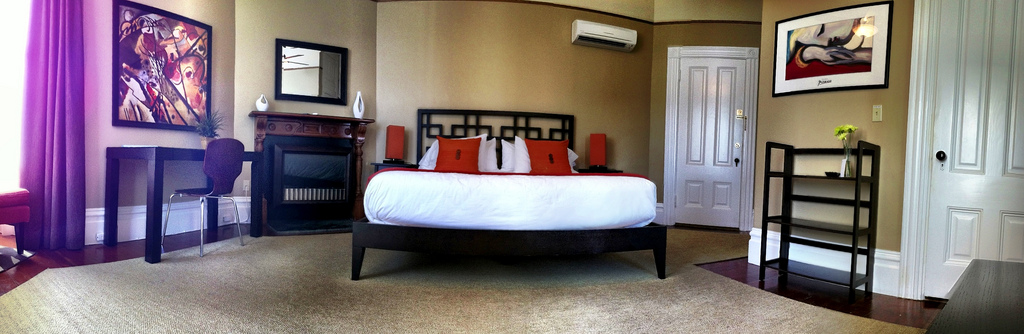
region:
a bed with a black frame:
[348, 109, 671, 284]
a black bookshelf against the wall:
[762, 141, 881, 293]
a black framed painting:
[105, 1, 213, 135]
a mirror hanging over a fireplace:
[248, 34, 378, 230]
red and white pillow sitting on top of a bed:
[354, 113, 659, 273]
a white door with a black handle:
[659, 43, 749, 231]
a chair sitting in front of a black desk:
[103, 137, 258, 267]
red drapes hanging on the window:
[19, 0, 87, 248]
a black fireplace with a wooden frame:
[248, 110, 376, 237]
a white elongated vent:
[570, 18, 638, 51]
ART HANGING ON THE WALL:
[106, 1, 223, 132]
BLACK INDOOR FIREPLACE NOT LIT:
[243, 107, 371, 238]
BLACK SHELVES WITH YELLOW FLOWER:
[760, 132, 881, 311]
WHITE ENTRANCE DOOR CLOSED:
[663, 46, 758, 234]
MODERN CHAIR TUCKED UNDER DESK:
[154, 122, 249, 258]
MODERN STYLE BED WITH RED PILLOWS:
[347, 102, 677, 277]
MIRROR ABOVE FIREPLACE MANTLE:
[271, 33, 352, 107]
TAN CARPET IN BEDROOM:
[11, 219, 934, 328]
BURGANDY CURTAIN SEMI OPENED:
[18, 0, 92, 256]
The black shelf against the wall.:
[759, 135, 874, 297]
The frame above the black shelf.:
[777, 1, 892, 90]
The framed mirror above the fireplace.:
[281, 38, 351, 106]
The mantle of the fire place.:
[255, 111, 370, 125]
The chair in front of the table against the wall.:
[158, 137, 250, 255]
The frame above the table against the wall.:
[116, 6, 216, 134]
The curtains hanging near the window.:
[15, 1, 89, 252]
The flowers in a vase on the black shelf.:
[834, 116, 860, 183]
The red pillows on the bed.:
[436, 137, 572, 173]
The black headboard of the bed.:
[417, 108, 572, 146]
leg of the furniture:
[98, 234, 118, 253]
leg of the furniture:
[206, 208, 222, 237]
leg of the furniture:
[231, 217, 276, 237]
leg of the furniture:
[354, 249, 371, 289]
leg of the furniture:
[643, 265, 666, 291]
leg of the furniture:
[842, 282, 862, 293]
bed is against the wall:
[346, 106, 667, 280]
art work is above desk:
[108, 0, 207, 130]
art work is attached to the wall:
[769, 0, 896, 95]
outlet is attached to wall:
[870, 103, 884, 120]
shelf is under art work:
[757, 137, 874, 306]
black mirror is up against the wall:
[273, 39, 347, 101]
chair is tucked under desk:
[159, 134, 248, 255]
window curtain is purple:
[17, 0, 85, 257]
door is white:
[898, 0, 1022, 305]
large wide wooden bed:
[350, 104, 673, 283]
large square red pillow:
[526, 138, 572, 174]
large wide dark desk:
[97, 144, 269, 271]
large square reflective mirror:
[274, 39, 357, 113]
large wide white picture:
[772, 2, 902, 95]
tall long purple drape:
[21, 0, 92, 261]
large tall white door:
[662, 43, 762, 239]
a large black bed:
[345, 85, 691, 288]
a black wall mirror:
[269, 37, 350, 115]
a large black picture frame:
[109, 4, 217, 134]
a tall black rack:
[750, 130, 887, 309]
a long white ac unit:
[570, 19, 640, 48]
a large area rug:
[0, 211, 866, 330]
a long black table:
[105, 136, 261, 263]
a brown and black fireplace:
[248, 107, 370, 238]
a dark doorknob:
[936, 145, 955, 164]